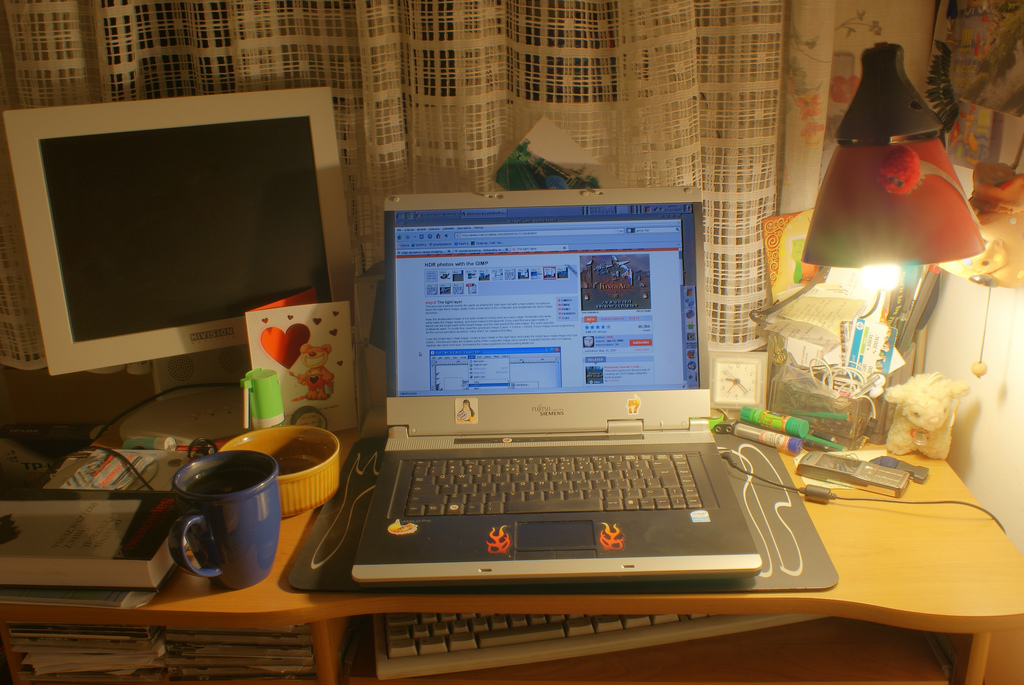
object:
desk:
[0, 361, 1024, 683]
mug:
[165, 449, 282, 591]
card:
[241, 286, 361, 435]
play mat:
[282, 432, 833, 595]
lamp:
[799, 40, 986, 271]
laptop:
[354, 184, 765, 593]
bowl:
[217, 424, 340, 516]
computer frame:
[0, 86, 361, 378]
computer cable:
[718, 455, 1005, 532]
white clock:
[709, 351, 767, 411]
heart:
[260, 322, 312, 369]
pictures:
[717, 443, 805, 579]